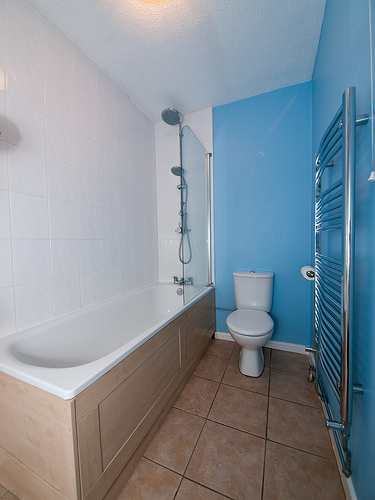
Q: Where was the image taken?
A: It was taken at the bathroom.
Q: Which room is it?
A: It is a bathroom.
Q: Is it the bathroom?
A: Yes, it is the bathroom.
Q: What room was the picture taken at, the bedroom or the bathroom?
A: It was taken at the bathroom.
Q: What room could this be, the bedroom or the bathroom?
A: It is the bathroom.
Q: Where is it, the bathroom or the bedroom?
A: It is the bathroom.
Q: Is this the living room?
A: No, it is the bathroom.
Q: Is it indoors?
A: Yes, it is indoors.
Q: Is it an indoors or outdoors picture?
A: It is indoors.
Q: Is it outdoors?
A: No, it is indoors.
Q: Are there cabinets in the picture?
A: No, there are no cabinets.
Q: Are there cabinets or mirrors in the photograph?
A: No, there are no cabinets or mirrors.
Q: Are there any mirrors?
A: No, there are no mirrors.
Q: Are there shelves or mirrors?
A: No, there are no mirrors or shelves.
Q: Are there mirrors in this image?
A: No, there are no mirrors.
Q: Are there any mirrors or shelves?
A: No, there are no mirrors or shelves.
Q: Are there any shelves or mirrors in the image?
A: No, there are no mirrors or shelves.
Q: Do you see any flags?
A: No, there are no flags.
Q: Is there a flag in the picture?
A: No, there are no flags.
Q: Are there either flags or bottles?
A: No, there are no flags or bottles.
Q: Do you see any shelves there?
A: No, there are no shelves.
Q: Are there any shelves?
A: No, there are no shelves.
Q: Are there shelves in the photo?
A: No, there are no shelves.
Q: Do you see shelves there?
A: No, there are no shelves.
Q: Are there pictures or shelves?
A: No, there are no shelves or pictures.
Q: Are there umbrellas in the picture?
A: No, there are no umbrellas.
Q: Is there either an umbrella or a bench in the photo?
A: No, there are no umbrellas or benches.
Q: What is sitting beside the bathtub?
A: The toilet is sitting beside the bathtub.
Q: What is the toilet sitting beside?
A: The toilet is sitting beside the tub.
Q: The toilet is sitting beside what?
A: The toilet is sitting beside the tub.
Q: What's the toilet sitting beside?
A: The toilet is sitting beside the tub.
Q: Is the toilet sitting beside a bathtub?
A: Yes, the toilet is sitting beside a bathtub.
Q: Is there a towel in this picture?
A: No, there are no towels.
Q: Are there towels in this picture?
A: No, there are no towels.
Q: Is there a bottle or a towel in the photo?
A: No, there are no towels or bottles.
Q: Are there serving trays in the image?
A: No, there are no serving trays.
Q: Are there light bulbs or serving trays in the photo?
A: No, there are no serving trays or light bulbs.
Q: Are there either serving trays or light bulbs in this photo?
A: No, there are no serving trays or light bulbs.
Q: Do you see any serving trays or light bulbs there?
A: No, there are no serving trays or light bulbs.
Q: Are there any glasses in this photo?
A: No, there are no glasses.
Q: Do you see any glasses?
A: No, there are no glasses.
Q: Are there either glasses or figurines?
A: No, there are no glasses or figurines.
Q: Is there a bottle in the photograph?
A: No, there are no bottles.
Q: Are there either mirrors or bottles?
A: No, there are no bottles or mirrors.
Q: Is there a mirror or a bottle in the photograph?
A: No, there are no bottles or mirrors.